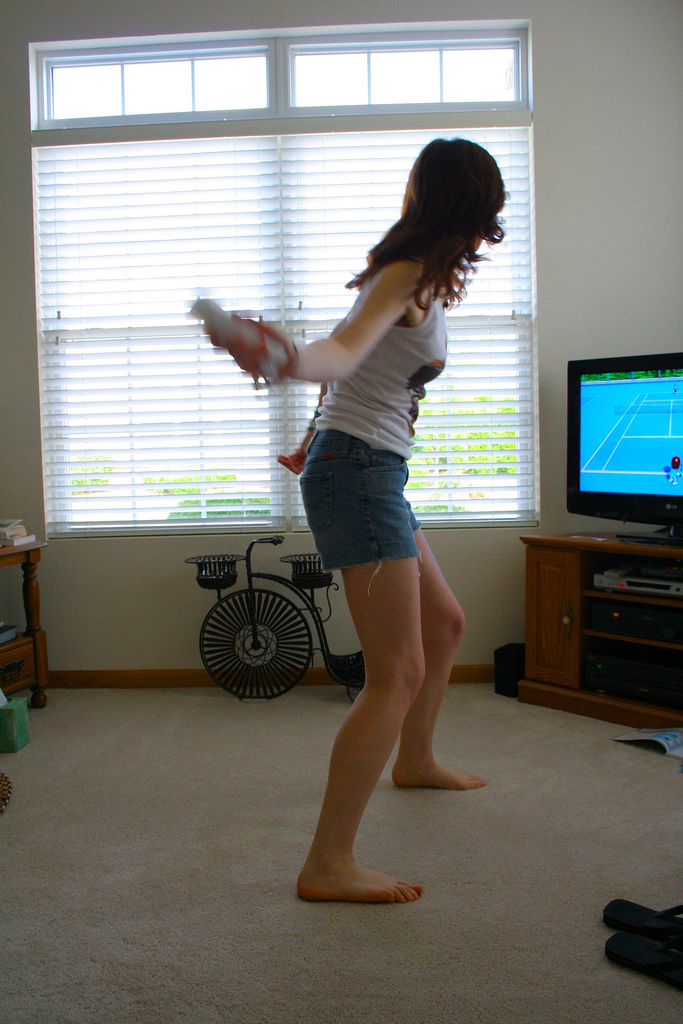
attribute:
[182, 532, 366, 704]
stand — decorative, bicycle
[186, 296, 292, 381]
remote — gaming console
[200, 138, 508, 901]
lady — caucasian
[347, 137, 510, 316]
hair — brown